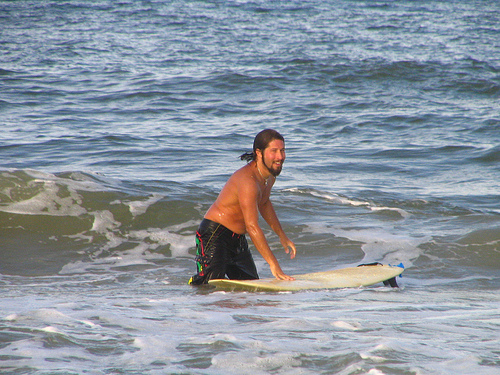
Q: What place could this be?
A: It is an ocean.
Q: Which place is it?
A: It is an ocean.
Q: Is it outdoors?
A: Yes, it is outdoors.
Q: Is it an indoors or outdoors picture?
A: It is outdoors.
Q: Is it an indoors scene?
A: No, it is outdoors.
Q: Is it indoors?
A: No, it is outdoors.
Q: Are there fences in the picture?
A: No, there are no fences.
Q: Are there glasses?
A: No, there are no glasses.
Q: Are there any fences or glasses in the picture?
A: No, there are no glasses or fences.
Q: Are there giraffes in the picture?
A: No, there are no giraffes.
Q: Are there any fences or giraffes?
A: No, there are no giraffes or fences.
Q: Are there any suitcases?
A: No, there are no suitcases.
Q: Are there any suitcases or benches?
A: No, there are no suitcases or benches.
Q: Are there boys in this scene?
A: No, there are no boys.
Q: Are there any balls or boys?
A: No, there are no boys or balls.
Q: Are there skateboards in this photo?
A: No, there are no skateboards.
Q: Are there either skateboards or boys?
A: No, there are no skateboards or boys.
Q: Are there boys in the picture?
A: No, there are no boys.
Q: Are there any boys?
A: No, there are no boys.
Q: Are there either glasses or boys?
A: No, there are no boys or glasses.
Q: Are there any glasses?
A: No, there are no glasses.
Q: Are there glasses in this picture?
A: No, there are no glasses.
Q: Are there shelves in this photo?
A: No, there are no shelves.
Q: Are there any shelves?
A: No, there are no shelves.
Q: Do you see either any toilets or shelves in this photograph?
A: No, there are no shelves or toilets.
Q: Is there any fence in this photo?
A: No, there are no fences.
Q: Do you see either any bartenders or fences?
A: No, there are no fences or bartenders.